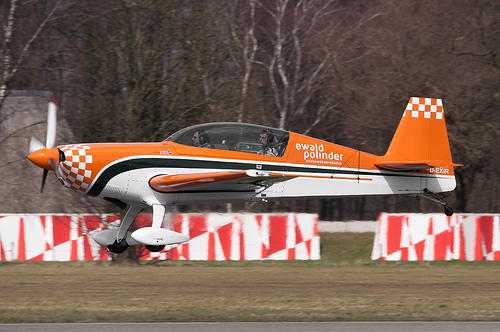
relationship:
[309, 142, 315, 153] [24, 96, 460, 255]
letter on airplane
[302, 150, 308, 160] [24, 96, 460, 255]
letter on airplane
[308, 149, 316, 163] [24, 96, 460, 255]
letter on airplane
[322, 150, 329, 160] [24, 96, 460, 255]
letter on airplane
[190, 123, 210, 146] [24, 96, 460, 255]
man in airplane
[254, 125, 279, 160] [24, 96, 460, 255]
man in airplane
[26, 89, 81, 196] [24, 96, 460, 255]
propeller in front of airplane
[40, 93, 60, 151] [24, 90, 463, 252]
blade of propeller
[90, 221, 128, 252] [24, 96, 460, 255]
wheel of airplane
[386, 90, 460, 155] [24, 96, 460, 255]
stabilizer of airplane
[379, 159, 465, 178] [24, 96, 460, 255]
stabilizer of airplane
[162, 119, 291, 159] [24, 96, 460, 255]
cockpit of airplane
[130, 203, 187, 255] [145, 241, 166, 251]
structure holding wheel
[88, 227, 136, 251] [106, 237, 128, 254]
structure holding wheel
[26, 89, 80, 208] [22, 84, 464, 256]
propeller on front of aircraft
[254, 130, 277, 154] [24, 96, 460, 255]
man inside airplane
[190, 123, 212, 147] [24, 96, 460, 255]
man inside airplane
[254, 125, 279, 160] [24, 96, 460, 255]
man flying airplane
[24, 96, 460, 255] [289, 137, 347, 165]
airplane has name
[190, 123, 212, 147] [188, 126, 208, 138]
man wearing headphones .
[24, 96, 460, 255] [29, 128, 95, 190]
airplane with nose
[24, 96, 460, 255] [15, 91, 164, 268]
airplane with propellers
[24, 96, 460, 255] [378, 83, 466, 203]
airplane with tail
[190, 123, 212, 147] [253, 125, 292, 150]
man in seat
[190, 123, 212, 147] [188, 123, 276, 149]
man wearing headphones.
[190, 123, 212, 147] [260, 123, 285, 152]
man in seat .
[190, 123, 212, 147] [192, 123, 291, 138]
man wearing headphones .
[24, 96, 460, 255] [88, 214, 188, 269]
airplane with wheel .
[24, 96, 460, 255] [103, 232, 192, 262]
airplane with wheel .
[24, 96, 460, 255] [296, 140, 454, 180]
airplane with letters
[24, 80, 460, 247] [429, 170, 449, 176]
airplane with letters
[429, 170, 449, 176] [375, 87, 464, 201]
letters on tail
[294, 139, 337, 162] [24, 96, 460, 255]
letters on airplane